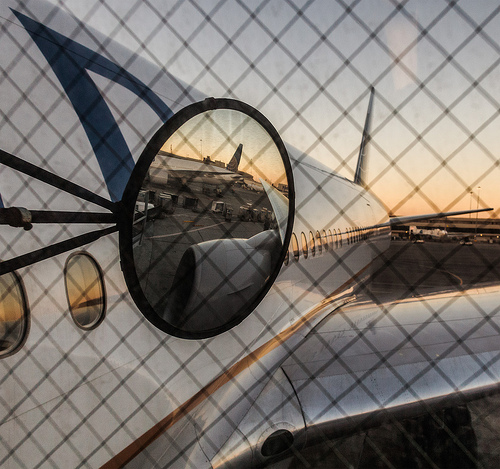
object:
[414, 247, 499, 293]
lines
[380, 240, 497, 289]
ground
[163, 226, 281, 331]
engine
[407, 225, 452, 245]
airplane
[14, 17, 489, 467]
plane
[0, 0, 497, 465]
airplane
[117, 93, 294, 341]
side view mirror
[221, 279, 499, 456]
wing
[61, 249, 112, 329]
window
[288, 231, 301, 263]
window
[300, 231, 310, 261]
window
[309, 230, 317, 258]
window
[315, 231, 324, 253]
window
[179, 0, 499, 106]
sky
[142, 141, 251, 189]
plane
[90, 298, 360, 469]
stripe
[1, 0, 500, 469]
fence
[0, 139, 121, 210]
pole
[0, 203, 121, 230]
pole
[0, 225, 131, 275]
pole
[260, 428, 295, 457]
circle